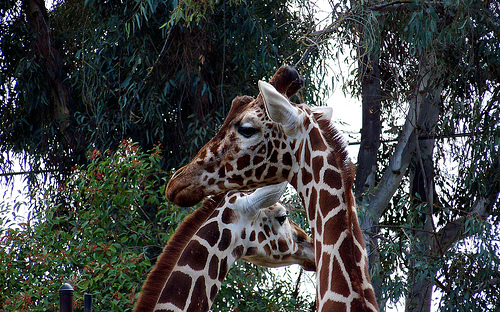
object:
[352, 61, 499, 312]
trunk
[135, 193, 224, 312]
mane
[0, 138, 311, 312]
bush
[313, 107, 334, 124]
ear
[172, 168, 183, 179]
nose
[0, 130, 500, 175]
powerline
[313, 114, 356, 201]
mane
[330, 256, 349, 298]
spots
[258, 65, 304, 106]
giraffe horns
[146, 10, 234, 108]
leaves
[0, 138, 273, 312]
flowers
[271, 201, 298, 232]
eye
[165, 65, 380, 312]
giraffe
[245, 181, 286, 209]
ear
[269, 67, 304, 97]
brown hair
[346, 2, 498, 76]
leaves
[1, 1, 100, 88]
leaves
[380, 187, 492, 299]
branch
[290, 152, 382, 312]
giraffe's neck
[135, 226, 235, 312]
giraffe's neck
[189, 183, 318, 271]
giraffe's head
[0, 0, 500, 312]
leafy tree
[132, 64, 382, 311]
two giraffes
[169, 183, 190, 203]
mouth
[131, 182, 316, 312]
giraffe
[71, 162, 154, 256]
leaves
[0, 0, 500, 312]
sky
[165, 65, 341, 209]
head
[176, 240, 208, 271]
spots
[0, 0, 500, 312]
woods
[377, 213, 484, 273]
space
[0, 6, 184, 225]
foilage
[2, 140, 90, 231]
space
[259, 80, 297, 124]
ear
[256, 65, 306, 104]
horn